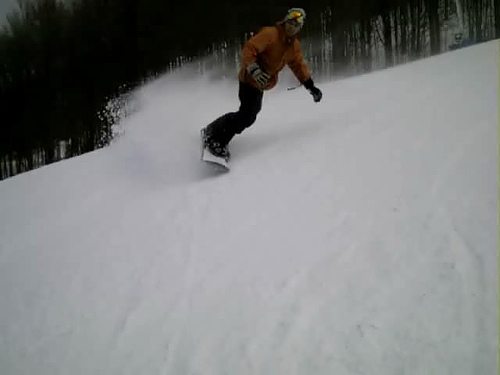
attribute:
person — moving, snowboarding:
[201, 3, 325, 160]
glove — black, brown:
[302, 72, 327, 106]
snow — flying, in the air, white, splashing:
[105, 53, 337, 176]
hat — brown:
[282, 4, 309, 26]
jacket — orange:
[237, 25, 312, 88]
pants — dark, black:
[206, 78, 264, 144]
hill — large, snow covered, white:
[2, 30, 499, 375]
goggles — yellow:
[283, 16, 305, 31]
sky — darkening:
[1, 3, 82, 34]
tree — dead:
[375, 1, 396, 71]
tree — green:
[23, 2, 69, 166]